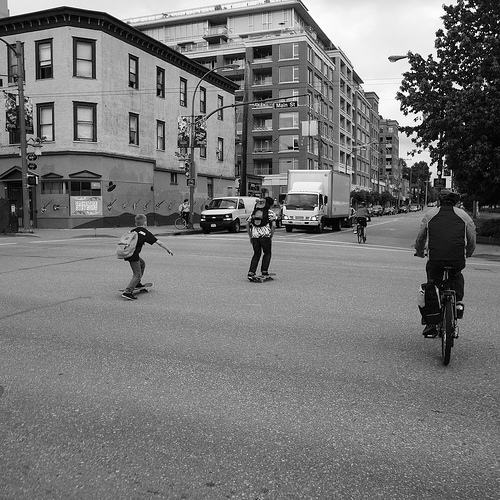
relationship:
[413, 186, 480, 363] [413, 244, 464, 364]
man on a bicycle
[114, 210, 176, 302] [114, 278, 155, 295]
boy on skateboard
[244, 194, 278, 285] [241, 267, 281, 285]
guy on skateboard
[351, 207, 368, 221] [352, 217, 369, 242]
man on bicycle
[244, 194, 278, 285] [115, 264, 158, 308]
guy on skateboard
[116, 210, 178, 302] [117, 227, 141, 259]
boy carrying backpack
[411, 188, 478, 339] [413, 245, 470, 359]
man has bicycle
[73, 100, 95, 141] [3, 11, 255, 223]
window of building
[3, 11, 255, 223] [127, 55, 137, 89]
building has window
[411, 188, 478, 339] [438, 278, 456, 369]
man on bicycle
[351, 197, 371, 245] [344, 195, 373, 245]
man riding bicycle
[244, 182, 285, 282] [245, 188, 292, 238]
guy carrying backpack